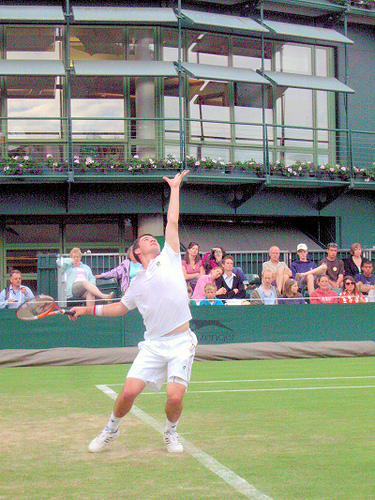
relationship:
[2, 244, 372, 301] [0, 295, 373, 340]
fans in stand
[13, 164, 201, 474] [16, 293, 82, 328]
tennis player has racket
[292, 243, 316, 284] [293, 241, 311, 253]
fan has hat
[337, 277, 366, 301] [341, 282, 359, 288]
woman wears sunglasses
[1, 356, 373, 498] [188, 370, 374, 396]
court has lines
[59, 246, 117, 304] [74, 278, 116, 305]
woman with crossed legs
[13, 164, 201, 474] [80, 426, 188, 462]
tennis player has shoes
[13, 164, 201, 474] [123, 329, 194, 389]
tennis player wears shorts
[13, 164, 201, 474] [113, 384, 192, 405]
tennis player bends knees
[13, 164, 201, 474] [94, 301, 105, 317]
tennis player has wrist band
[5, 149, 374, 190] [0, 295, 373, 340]
flowers above stand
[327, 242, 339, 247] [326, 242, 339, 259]
sunglasses on head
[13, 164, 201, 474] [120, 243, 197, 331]
tennis player has shirt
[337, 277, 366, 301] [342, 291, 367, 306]
woman has shirt